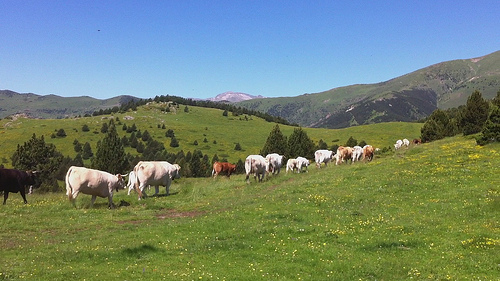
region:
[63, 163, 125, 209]
white cow in green pasture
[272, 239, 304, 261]
tiny flowers in the grass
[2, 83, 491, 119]
mountains in the distance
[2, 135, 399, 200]
a herd of cows walking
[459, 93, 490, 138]
a small green shrub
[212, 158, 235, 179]
brown cow in the distance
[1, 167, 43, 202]
a darkly colored cow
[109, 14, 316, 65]
a clear blue sky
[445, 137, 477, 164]
yellow flowers on the hill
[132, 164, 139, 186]
the tail of a white cow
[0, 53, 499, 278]
A large grassy landscape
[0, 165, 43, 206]
A black cow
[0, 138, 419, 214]
A line of cattle in a field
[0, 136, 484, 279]
yellow flowers in the field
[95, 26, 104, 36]
A bird in the sky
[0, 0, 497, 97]
A clear, blue sky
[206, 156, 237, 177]
A brown cow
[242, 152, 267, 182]
A white cow in the field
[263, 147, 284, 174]
A white cow in the field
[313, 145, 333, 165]
A white cow in the field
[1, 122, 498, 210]
herd of cows in field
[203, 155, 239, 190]
brown cow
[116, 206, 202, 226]
dead spot of field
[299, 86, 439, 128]
large patch of trees on far hill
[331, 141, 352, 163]
brown and white cow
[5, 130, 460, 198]
mostly white cows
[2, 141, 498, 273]
yellow flowers amongst the grass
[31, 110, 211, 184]
patches of trees and shrubs amongst field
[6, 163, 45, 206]
black cow walking alone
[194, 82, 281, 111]
large hill in distance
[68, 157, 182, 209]
two white cows walking up green hill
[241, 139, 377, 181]
large group of white and brown cows walking up green hill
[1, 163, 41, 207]
black cow walking up green hill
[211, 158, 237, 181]
brown cow walking up green hill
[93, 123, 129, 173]
triangular green tree on green hill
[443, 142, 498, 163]
patch of yellow flowers on green hill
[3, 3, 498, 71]
blue sky over green hill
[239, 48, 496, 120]
green mountain next to green hill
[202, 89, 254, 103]
brown mountain behind green hill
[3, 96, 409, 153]
green hill with green triangular trees on it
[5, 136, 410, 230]
cattle in a field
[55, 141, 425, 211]
bunch of white cattles in a field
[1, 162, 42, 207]
black cattle in the back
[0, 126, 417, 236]
cattle in line in a field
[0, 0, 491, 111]
aky is blue and clear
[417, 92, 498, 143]
bunch of bushes in the right side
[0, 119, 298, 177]
bunch of bushes in the bottom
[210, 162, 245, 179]
dark brown cattle walking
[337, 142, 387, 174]
two light brown cattle in a field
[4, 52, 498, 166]
big large mountains in the back